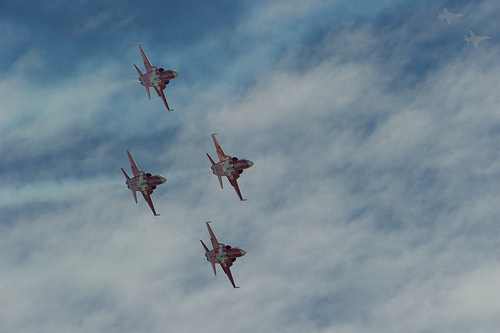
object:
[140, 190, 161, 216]
right wing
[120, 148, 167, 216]
plane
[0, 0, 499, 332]
sky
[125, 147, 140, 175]
wing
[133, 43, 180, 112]
plane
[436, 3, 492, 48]
jets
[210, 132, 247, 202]
wings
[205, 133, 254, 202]
plane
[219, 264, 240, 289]
wing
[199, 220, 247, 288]
plane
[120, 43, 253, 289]
jets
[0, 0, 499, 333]
cloud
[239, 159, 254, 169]
nose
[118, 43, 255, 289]
angle